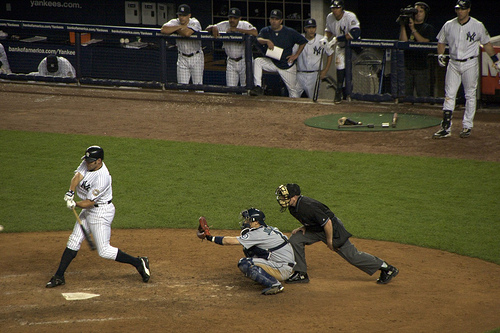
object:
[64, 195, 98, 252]
bat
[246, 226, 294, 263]
waist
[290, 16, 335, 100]
player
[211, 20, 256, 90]
uniform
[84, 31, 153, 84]
cat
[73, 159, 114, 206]
jersey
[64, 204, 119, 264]
pants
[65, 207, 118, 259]
pinstripes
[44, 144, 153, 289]
baseball batter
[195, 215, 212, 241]
mitt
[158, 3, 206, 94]
baseball player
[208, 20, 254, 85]
uniform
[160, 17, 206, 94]
uniform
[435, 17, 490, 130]
uniform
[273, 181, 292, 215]
mask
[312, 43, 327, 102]
bat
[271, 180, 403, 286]
baseball player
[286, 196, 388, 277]
uniform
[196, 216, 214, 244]
glove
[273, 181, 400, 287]
umpire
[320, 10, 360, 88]
player uniform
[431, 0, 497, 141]
player uniform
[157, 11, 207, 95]
player uniform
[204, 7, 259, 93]
baseball player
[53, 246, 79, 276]
sock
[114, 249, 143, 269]
sock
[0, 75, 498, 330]
field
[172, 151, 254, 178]
turf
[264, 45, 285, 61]
paper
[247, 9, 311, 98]
man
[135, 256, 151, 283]
shoe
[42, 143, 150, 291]
batter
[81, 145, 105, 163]
helmet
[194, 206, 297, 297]
player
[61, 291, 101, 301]
home plate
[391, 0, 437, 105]
cameraman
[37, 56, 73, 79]
uniform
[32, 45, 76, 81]
player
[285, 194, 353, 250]
clothing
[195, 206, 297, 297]
catcher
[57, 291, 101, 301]
plate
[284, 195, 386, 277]
dressed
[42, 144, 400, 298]
game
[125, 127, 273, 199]
field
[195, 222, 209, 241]
hand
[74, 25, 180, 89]
railing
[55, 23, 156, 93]
pen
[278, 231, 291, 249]
strap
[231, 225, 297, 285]
uniform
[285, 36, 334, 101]
uniform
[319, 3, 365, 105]
player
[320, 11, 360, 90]
uniform